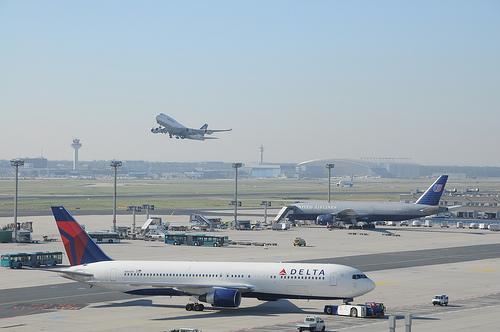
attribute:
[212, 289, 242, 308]
engine —  blue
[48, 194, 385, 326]
airplane —  white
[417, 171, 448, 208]
tail — blue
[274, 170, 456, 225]
airplane —   gray 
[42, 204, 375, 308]
airplane —  white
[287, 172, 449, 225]
airplane — gray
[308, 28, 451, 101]
sky — blue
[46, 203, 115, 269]
tail — blue, red